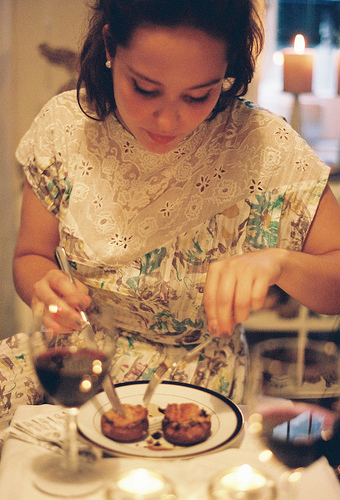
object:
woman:
[0, 0, 339, 435]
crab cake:
[162, 399, 212, 444]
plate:
[74, 376, 243, 461]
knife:
[54, 243, 126, 419]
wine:
[34, 342, 111, 406]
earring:
[103, 52, 118, 73]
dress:
[0, 94, 332, 433]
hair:
[73, 0, 264, 121]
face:
[113, 24, 228, 153]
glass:
[27, 291, 118, 498]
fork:
[141, 327, 216, 409]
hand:
[200, 247, 281, 338]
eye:
[181, 88, 211, 110]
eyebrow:
[183, 77, 225, 91]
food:
[100, 393, 149, 442]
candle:
[282, 30, 314, 95]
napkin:
[9, 400, 79, 454]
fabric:
[57, 111, 242, 256]